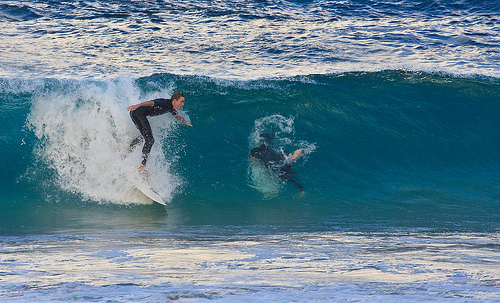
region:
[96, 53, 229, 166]
surfer in the water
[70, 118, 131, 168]
white water splashing next to surfer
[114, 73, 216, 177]
surfer facing the right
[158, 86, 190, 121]
head of the surfer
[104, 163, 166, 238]
board below the surfer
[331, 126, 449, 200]
blue ocean next to the surfer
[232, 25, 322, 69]
ripples in the water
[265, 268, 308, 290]
water in the foreground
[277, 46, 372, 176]
wave forming in the water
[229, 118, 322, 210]
being in the water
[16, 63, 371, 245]
guys surfing on wave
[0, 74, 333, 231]
guys surfing in ocean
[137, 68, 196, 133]
man wearing wet suite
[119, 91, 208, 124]
man with arms out to side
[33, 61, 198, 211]
white water on wave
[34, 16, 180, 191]
breaking wave in ocean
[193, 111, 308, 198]
man on board on wave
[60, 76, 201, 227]
man standing on board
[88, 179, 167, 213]
white short board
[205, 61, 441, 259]
unbroken section of wave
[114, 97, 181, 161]
black short sleeved rashguard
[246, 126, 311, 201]
Person under the water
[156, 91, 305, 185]
Surfer looking at swimmer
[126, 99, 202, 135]
Surfer arms are outstretched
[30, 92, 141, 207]
White ripples in the water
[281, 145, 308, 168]
Swimmer foot sticking up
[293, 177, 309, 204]
Swimmer foot is down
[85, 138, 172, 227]
Surfboard is white and under water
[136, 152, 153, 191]
Surfer is bare foot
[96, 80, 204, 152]
Surfer is bent over slightly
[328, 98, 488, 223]
Greenish color to the water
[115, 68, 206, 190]
man in the water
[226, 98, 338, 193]
thing in the water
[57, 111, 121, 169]
white wave in the water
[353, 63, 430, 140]
wave forming on the water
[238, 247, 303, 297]
still water in the foreground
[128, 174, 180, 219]
white board under the surfer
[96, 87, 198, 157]
man in a wetsuit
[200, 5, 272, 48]
still water behind the wave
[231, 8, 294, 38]
ripples in the water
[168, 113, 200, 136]
left arm of the man